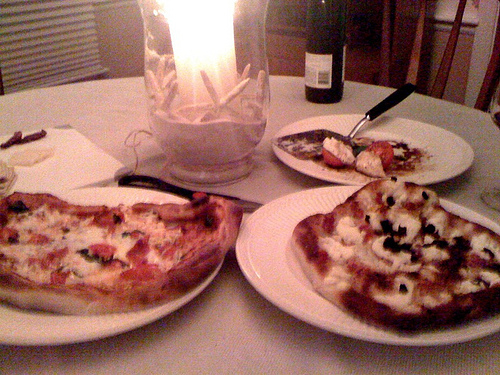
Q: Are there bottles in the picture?
A: Yes, there is a bottle.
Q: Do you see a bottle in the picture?
A: Yes, there is a bottle.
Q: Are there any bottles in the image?
A: Yes, there is a bottle.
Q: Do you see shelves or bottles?
A: Yes, there is a bottle.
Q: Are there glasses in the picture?
A: No, there are no glasses.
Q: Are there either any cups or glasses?
A: No, there are no glasses or cups.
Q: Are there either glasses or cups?
A: No, there are no glasses or cups.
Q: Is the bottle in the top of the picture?
A: Yes, the bottle is in the top of the image.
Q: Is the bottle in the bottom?
A: No, the bottle is in the top of the image.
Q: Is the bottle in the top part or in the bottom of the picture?
A: The bottle is in the top of the image.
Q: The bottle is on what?
A: The bottle is on the table.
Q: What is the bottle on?
A: The bottle is on the table.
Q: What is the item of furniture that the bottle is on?
A: The piece of furniture is a table.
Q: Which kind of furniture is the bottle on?
A: The bottle is on the table.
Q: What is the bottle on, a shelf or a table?
A: The bottle is on a table.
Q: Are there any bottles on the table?
A: Yes, there is a bottle on the table.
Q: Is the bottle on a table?
A: Yes, the bottle is on a table.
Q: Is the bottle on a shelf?
A: No, the bottle is on a table.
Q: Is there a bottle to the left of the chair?
A: Yes, there is a bottle to the left of the chair.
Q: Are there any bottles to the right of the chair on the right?
A: No, the bottle is to the left of the chair.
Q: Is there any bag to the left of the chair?
A: No, there is a bottle to the left of the chair.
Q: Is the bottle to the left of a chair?
A: Yes, the bottle is to the left of a chair.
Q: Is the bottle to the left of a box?
A: No, the bottle is to the left of a chair.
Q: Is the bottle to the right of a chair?
A: No, the bottle is to the left of a chair.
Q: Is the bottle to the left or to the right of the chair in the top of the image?
A: The bottle is to the left of the chair.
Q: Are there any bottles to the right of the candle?
A: Yes, there is a bottle to the right of the candle.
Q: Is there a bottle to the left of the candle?
A: No, the bottle is to the right of the candle.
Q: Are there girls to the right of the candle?
A: No, there is a bottle to the right of the candle.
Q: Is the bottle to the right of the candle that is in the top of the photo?
A: Yes, the bottle is to the right of the candle.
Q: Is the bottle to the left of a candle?
A: No, the bottle is to the right of a candle.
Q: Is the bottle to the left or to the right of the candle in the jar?
A: The bottle is to the right of the candle.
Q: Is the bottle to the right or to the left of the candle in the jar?
A: The bottle is to the right of the candle.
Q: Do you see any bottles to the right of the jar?
A: Yes, there is a bottle to the right of the jar.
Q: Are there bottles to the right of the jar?
A: Yes, there is a bottle to the right of the jar.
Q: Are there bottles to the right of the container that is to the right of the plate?
A: Yes, there is a bottle to the right of the jar.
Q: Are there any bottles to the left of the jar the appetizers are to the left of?
A: No, the bottle is to the right of the jar.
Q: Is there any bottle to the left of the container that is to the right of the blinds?
A: No, the bottle is to the right of the jar.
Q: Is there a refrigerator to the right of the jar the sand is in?
A: No, there is a bottle to the right of the jar.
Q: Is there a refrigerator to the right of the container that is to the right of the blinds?
A: No, there is a bottle to the right of the jar.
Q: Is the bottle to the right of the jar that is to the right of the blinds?
A: Yes, the bottle is to the right of the jar.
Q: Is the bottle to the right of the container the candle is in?
A: Yes, the bottle is to the right of the jar.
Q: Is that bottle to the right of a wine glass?
A: No, the bottle is to the right of the jar.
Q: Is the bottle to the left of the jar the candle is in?
A: No, the bottle is to the right of the jar.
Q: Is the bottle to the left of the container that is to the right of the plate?
A: No, the bottle is to the right of the jar.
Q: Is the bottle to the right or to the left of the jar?
A: The bottle is to the right of the jar.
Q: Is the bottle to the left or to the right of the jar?
A: The bottle is to the right of the jar.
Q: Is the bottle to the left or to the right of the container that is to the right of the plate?
A: The bottle is to the right of the jar.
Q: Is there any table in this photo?
A: Yes, there is a table.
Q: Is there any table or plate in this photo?
A: Yes, there is a table.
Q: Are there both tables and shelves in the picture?
A: No, there is a table but no shelves.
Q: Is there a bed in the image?
A: No, there are no beds.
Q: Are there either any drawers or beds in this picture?
A: No, there are no beds or drawers.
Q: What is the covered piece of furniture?
A: The piece of furniture is a table.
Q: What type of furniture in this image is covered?
A: The furniture is a table.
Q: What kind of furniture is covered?
A: The furniture is a table.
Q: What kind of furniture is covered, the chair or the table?
A: The table is covered.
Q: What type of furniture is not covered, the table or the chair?
A: The chair is not covered.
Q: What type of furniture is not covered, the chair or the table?
A: The chair is not covered.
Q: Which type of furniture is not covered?
A: The furniture is a chair.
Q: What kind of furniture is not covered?
A: The furniture is a chair.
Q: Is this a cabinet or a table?
A: This is a table.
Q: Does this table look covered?
A: Yes, the table is covered.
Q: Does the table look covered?
A: Yes, the table is covered.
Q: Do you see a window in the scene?
A: Yes, there is a window.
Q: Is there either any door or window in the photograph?
A: Yes, there is a window.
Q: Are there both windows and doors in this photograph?
A: No, there is a window but no doors.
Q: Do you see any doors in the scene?
A: No, there are no doors.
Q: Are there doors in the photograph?
A: No, there are no doors.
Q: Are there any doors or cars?
A: No, there are no doors or cars.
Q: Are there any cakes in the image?
A: No, there are no cakes.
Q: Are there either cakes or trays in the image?
A: No, there are no cakes or trays.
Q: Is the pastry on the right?
A: Yes, the pastry is on the right of the image.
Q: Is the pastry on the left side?
A: No, the pastry is on the right of the image.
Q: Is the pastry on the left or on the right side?
A: The pastry is on the right of the image.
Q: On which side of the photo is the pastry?
A: The pastry is on the right of the image.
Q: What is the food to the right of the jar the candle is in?
A: The food is a pastry.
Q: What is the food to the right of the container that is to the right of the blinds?
A: The food is a pastry.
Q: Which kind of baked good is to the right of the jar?
A: The food is a pastry.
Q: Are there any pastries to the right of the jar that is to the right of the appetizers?
A: Yes, there is a pastry to the right of the jar.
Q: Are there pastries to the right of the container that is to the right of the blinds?
A: Yes, there is a pastry to the right of the jar.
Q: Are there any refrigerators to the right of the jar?
A: No, there is a pastry to the right of the jar.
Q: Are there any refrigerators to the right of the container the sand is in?
A: No, there is a pastry to the right of the jar.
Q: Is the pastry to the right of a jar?
A: Yes, the pastry is to the right of a jar.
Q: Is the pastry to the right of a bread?
A: No, the pastry is to the right of a jar.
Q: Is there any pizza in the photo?
A: Yes, there is a pizza.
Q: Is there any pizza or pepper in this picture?
A: Yes, there is a pizza.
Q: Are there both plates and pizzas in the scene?
A: Yes, there are both a pizza and a plate.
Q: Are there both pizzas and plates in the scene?
A: Yes, there are both a pizza and a plate.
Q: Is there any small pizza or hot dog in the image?
A: Yes, there is a small pizza.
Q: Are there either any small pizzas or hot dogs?
A: Yes, there is a small pizza.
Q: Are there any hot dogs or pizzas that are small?
A: Yes, the pizza is small.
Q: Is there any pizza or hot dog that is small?
A: Yes, the pizza is small.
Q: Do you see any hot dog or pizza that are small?
A: Yes, the pizza is small.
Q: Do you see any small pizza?
A: Yes, there is a small pizza.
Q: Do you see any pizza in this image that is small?
A: Yes, there is a pizza that is small.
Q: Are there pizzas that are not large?
A: Yes, there is a small pizza.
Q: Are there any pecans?
A: No, there are no pecans.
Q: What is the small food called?
A: The food is a pizza.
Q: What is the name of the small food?
A: The food is a pizza.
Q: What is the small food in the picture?
A: The food is a pizza.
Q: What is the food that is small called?
A: The food is a pizza.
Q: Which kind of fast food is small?
A: The fast food is a pizza.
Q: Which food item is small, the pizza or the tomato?
A: The pizza is small.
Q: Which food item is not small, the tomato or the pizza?
A: The tomato is not small.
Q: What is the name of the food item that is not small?
A: The food item is a tomato.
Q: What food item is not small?
A: The food item is a tomato.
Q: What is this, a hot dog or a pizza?
A: This is a pizza.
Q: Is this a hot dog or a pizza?
A: This is a pizza.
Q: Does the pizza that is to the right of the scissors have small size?
A: Yes, the pizza is small.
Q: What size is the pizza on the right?
A: The pizza is small.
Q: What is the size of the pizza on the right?
A: The pizza is small.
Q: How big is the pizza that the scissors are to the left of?
A: The pizza is small.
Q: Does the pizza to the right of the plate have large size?
A: No, the pizza is small.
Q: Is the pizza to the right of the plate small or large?
A: The pizza is small.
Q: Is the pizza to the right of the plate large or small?
A: The pizza is small.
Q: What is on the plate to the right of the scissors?
A: The pizza is on the plate.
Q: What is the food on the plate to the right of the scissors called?
A: The food is a pizza.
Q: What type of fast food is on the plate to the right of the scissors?
A: The food is a pizza.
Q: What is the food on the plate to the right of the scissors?
A: The food is a pizza.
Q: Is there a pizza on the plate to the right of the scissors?
A: Yes, there is a pizza on the plate.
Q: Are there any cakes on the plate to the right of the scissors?
A: No, there is a pizza on the plate.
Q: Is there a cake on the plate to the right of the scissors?
A: No, there is a pizza on the plate.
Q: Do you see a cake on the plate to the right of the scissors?
A: No, there is a pizza on the plate.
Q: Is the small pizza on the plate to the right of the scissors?
A: Yes, the pizza is on the plate.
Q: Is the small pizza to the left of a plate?
A: No, the pizza is to the right of a plate.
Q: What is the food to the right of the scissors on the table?
A: The food is a pizza.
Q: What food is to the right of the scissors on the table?
A: The food is a pizza.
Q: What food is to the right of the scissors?
A: The food is a pizza.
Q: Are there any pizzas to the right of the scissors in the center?
A: Yes, there is a pizza to the right of the scissors.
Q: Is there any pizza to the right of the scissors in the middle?
A: Yes, there is a pizza to the right of the scissors.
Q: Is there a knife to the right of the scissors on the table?
A: No, there is a pizza to the right of the scissors.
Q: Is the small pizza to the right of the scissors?
A: Yes, the pizza is to the right of the scissors.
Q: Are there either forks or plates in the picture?
A: Yes, there is a plate.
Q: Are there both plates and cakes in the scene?
A: No, there is a plate but no cakes.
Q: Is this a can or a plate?
A: This is a plate.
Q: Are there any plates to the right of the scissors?
A: Yes, there is a plate to the right of the scissors.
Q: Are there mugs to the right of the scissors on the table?
A: No, there is a plate to the right of the scissors.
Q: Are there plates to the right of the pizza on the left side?
A: Yes, there is a plate to the right of the pizza.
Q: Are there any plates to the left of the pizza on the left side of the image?
A: No, the plate is to the right of the pizza.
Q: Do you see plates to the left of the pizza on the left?
A: No, the plate is to the right of the pizza.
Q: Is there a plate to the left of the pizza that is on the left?
A: No, the plate is to the right of the pizza.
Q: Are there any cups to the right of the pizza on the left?
A: No, there is a plate to the right of the pizza.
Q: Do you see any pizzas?
A: Yes, there is a pizza.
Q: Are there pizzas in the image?
A: Yes, there is a pizza.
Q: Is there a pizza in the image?
A: Yes, there is a pizza.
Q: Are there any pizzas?
A: Yes, there is a pizza.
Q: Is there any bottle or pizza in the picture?
A: Yes, there is a pizza.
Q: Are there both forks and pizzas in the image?
A: No, there is a pizza but no forks.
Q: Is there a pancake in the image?
A: No, there are no pancakes.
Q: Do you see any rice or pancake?
A: No, there are no pancakes or rice.